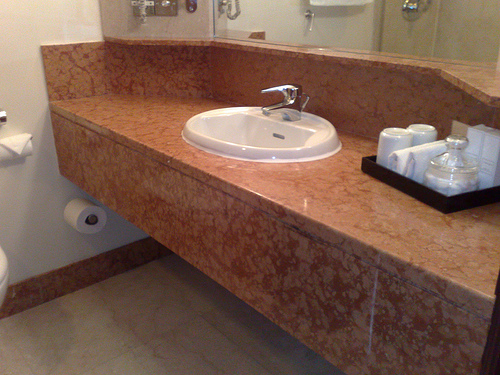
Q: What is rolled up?
A: Toilet paper.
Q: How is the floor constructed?
A: Tiles.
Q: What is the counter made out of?
A: Marble.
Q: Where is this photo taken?
A: A bathroom.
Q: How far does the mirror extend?
A: All the way across the counter.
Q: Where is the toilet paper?
A: On the wall in front of the counter and underneath.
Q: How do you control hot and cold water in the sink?
A: Move the lever left and right.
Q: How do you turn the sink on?
A: Pull up on the lever above the faucet.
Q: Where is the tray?
A: To the right of the sink.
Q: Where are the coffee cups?
A: On the tray.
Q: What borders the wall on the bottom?
A: Red trim the same pattern as the counter.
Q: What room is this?
A: Bathroom.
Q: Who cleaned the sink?
A: Housekeeper.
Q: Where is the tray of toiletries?
A: On the sink.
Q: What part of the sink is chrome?
A: Faucet.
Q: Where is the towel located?
A: In a tray.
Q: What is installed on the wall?
A: Toilet paper holder.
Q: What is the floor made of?
A: Tiles.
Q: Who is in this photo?
A: No One.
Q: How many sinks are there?
A: One.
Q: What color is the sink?
A: White.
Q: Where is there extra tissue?
A: Under the countertop.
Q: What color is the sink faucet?
A: Silver.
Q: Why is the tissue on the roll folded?
A: To look fancy.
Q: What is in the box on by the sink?
A: Stationery.